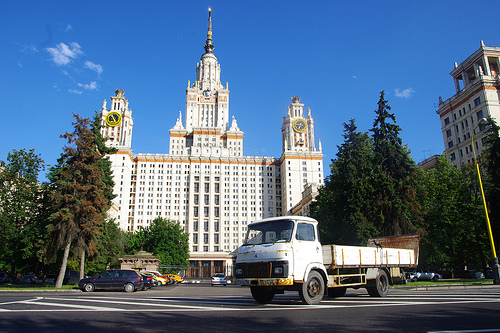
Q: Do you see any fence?
A: No, there are no fences.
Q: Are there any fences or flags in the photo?
A: No, there are no fences or flags.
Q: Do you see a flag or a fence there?
A: No, there are no fences or flags.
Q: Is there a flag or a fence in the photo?
A: No, there are no fences or flags.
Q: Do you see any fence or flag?
A: No, there are no fences or flags.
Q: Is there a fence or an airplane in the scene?
A: No, there are no fences or airplanes.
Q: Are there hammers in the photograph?
A: No, there are no hammers.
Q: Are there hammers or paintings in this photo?
A: No, there are no hammers or paintings.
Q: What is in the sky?
A: The clouds are in the sky.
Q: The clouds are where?
A: The clouds are in the sky.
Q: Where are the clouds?
A: The clouds are in the sky.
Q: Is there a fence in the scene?
A: No, there are no fences.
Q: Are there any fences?
A: No, there are no fences.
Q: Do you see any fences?
A: No, there are no fences.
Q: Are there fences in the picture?
A: No, there are no fences.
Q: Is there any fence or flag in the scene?
A: No, there are no fences or flags.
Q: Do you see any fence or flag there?
A: No, there are no fences or flags.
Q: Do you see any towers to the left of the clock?
A: Yes, there is a tower to the left of the clock.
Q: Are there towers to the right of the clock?
A: No, the tower is to the left of the clock.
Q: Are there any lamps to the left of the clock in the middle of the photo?
A: No, there is a tower to the left of the clock.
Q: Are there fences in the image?
A: No, there are no fences.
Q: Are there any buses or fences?
A: No, there are no fences or buses.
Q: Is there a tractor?
A: No, there are no tractors.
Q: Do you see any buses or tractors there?
A: No, there are no tractors or buses.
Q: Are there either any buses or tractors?
A: No, there are no tractors or buses.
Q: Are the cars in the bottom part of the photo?
A: Yes, the cars are in the bottom of the image.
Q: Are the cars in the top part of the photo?
A: No, the cars are in the bottom of the image.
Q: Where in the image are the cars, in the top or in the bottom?
A: The cars are in the bottom of the image.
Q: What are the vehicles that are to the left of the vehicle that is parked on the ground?
A: The vehicles are cars.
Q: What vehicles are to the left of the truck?
A: The vehicles are cars.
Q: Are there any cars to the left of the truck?
A: Yes, there are cars to the left of the truck.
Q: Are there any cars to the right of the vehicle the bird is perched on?
A: No, the cars are to the left of the truck.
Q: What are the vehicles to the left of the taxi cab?
A: The vehicles are cars.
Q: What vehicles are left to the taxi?
A: The vehicles are cars.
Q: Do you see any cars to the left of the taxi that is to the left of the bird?
A: Yes, there are cars to the left of the cab.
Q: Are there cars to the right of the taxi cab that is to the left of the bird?
A: No, the cars are to the left of the cab.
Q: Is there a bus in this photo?
A: No, there are no buses.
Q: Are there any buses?
A: No, there are no buses.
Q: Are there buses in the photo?
A: No, there are no buses.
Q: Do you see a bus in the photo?
A: No, there are no buses.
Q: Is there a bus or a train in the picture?
A: No, there are no buses or trains.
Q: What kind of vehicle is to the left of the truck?
A: The vehicle is a car.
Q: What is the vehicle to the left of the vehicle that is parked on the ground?
A: The vehicle is a car.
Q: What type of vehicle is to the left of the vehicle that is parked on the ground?
A: The vehicle is a car.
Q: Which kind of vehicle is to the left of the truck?
A: The vehicle is a car.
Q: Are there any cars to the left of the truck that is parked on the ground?
A: Yes, there is a car to the left of the truck.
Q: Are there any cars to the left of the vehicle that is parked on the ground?
A: Yes, there is a car to the left of the truck.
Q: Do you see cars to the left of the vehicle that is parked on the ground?
A: Yes, there is a car to the left of the truck.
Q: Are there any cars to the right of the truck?
A: No, the car is to the left of the truck.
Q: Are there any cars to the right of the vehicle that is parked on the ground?
A: No, the car is to the left of the truck.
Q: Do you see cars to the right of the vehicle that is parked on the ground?
A: No, the car is to the left of the truck.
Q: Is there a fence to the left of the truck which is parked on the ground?
A: No, there is a car to the left of the truck.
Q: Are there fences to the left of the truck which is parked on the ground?
A: No, there is a car to the left of the truck.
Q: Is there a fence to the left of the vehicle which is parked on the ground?
A: No, there is a car to the left of the truck.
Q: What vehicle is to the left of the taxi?
A: The vehicle is a car.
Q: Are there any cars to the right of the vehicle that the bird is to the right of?
A: No, the car is to the left of the cab.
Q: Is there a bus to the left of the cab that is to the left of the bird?
A: No, there is a car to the left of the cab.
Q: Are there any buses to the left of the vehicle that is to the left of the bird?
A: No, there is a car to the left of the cab.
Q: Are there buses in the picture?
A: No, there are no buses.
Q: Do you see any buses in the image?
A: No, there are no buses.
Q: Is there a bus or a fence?
A: No, there are no buses or fences.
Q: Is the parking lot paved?
A: Yes, the parking lot is paved.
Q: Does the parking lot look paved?
A: Yes, the parking lot is paved.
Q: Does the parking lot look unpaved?
A: No, the parking lot is paved.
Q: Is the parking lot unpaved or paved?
A: The parking lot is paved.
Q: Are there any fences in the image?
A: No, there are no fences.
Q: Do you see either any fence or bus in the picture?
A: No, there are no fences or buses.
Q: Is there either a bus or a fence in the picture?
A: No, there are no fences or buses.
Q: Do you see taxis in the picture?
A: Yes, there is a taxi.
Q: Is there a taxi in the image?
A: Yes, there is a taxi.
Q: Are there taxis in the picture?
A: Yes, there is a taxi.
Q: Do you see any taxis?
A: Yes, there is a taxi.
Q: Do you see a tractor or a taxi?
A: Yes, there is a taxi.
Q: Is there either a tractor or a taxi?
A: Yes, there is a taxi.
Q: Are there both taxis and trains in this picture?
A: No, there is a taxi but no trains.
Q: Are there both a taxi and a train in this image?
A: No, there is a taxi but no trains.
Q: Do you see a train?
A: No, there are no trains.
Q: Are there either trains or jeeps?
A: No, there are no trains or jeeps.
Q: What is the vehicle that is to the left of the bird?
A: The vehicle is a taxi.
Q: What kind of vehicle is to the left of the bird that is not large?
A: The vehicle is a taxi.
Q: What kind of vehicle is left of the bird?
A: The vehicle is a taxi.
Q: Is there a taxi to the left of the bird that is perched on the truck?
A: Yes, there is a taxi to the left of the bird.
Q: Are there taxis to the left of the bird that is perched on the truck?
A: Yes, there is a taxi to the left of the bird.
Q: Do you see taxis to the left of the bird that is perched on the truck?
A: Yes, there is a taxi to the left of the bird.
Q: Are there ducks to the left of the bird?
A: No, there is a taxi to the left of the bird.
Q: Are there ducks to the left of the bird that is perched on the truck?
A: No, there is a taxi to the left of the bird.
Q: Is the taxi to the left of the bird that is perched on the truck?
A: Yes, the taxi is to the left of the bird.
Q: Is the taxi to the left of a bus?
A: No, the taxi is to the left of the bird.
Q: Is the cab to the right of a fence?
A: No, the cab is to the right of a car.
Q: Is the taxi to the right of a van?
A: No, the taxi is to the right of the car.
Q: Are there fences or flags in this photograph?
A: No, there are no fences or flags.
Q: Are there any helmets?
A: No, there are no helmets.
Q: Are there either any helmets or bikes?
A: No, there are no helmets or bikes.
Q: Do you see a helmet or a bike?
A: No, there are no helmets or bikes.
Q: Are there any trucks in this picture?
A: Yes, there is a truck.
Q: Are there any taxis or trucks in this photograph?
A: Yes, there is a truck.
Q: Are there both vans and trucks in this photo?
A: No, there is a truck but no vans.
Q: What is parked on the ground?
A: The truck is parked on the ground.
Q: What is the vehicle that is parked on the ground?
A: The vehicle is a truck.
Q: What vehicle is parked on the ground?
A: The vehicle is a truck.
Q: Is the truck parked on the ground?
A: Yes, the truck is parked on the ground.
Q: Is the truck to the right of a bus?
A: No, the truck is to the right of the car.